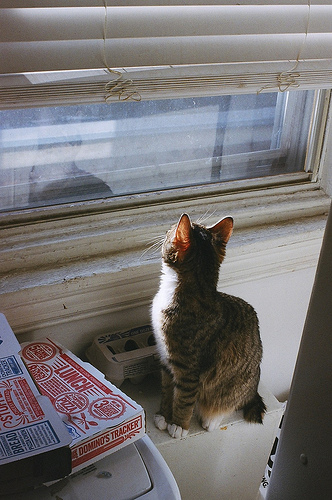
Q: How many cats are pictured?
A: One.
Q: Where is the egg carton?
A: Behind the cat.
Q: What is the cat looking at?
A: Reflection.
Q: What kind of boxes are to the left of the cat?
A: Pizza.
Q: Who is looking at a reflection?
A: The cat.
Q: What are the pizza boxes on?
A: The garbage.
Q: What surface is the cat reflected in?
A: The window.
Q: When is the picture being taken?
A: Daytime.